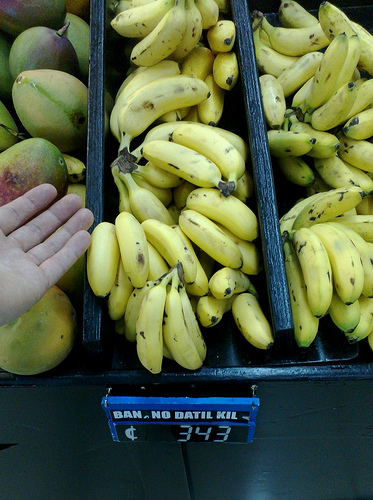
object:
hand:
[0, 182, 96, 329]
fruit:
[1, 137, 69, 237]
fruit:
[66, 183, 87, 210]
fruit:
[55, 250, 87, 296]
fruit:
[1, 284, 77, 375]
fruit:
[84, 221, 121, 299]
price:
[177, 425, 232, 443]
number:
[177, 425, 193, 443]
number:
[195, 426, 212, 441]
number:
[213, 425, 232, 443]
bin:
[98, 0, 270, 372]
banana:
[185, 188, 259, 241]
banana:
[170, 126, 245, 190]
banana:
[207, 19, 236, 53]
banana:
[118, 77, 210, 154]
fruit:
[12, 69, 88, 155]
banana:
[129, 0, 187, 67]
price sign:
[100, 384, 260, 446]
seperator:
[80, 0, 105, 344]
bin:
[0, 1, 100, 380]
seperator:
[229, 0, 294, 338]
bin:
[244, 0, 371, 354]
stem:
[229, 173, 239, 193]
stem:
[118, 133, 132, 155]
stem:
[175, 1, 185, 13]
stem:
[161, 273, 171, 285]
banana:
[134, 270, 173, 376]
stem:
[172, 271, 180, 291]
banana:
[162, 266, 204, 372]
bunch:
[111, 155, 184, 227]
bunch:
[110, 58, 212, 164]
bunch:
[110, 0, 220, 68]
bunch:
[282, 220, 372, 351]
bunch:
[123, 261, 207, 375]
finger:
[0, 184, 56, 230]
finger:
[7, 192, 83, 248]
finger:
[29, 207, 95, 262]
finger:
[40, 228, 91, 286]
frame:
[99, 397, 260, 443]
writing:
[112, 410, 239, 421]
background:
[0, 0, 373, 500]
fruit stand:
[0, 0, 372, 500]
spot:
[172, 84, 184, 93]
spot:
[122, 131, 125, 136]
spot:
[141, 99, 154, 109]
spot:
[154, 93, 165, 98]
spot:
[191, 84, 198, 91]